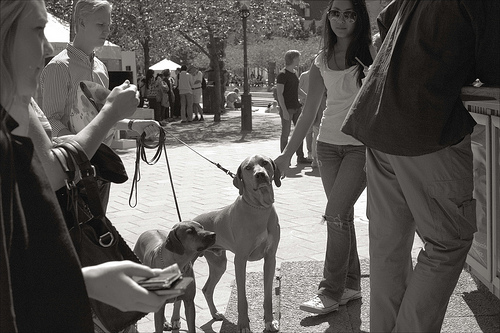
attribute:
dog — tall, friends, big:
[193, 152, 284, 329]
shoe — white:
[293, 295, 344, 317]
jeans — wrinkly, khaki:
[358, 139, 476, 332]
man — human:
[34, 2, 165, 170]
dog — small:
[135, 224, 219, 328]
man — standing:
[349, 4, 500, 332]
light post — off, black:
[237, 8, 256, 141]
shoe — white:
[339, 285, 364, 306]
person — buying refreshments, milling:
[137, 60, 166, 115]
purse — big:
[52, 138, 157, 328]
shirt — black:
[345, 5, 498, 156]